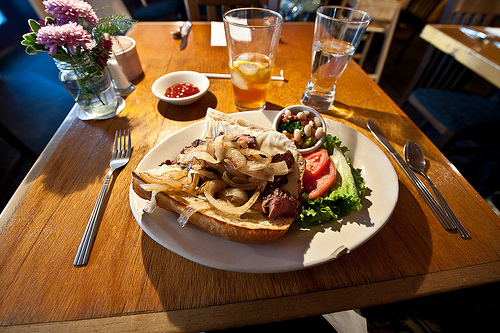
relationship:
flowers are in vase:
[20, 0, 133, 75] [50, 50, 126, 125]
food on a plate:
[135, 110, 367, 233] [129, 105, 402, 276]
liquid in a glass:
[231, 56, 271, 108] [220, 9, 280, 110]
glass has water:
[220, 9, 280, 110] [302, 4, 373, 110]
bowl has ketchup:
[152, 70, 208, 104] [164, 81, 198, 97]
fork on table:
[75, 125, 132, 267] [2, 11, 499, 323]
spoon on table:
[400, 138, 471, 240] [2, 11, 499, 323]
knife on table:
[365, 117, 456, 232] [2, 11, 499, 323]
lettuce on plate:
[284, 132, 368, 226] [129, 105, 402, 276]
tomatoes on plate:
[304, 148, 338, 199] [129, 105, 402, 276]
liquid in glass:
[231, 56, 271, 108] [220, 9, 280, 110]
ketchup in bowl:
[164, 81, 198, 97] [152, 70, 208, 104]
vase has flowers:
[50, 50, 126, 125] [20, 0, 133, 75]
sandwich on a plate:
[132, 106, 304, 240] [129, 105, 402, 276]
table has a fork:
[2, 11, 499, 323] [75, 125, 132, 267]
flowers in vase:
[20, 0, 133, 75] [50, 50, 126, 125]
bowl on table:
[152, 70, 208, 104] [2, 11, 499, 323]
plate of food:
[129, 105, 402, 276] [135, 110, 367, 233]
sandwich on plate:
[132, 106, 304, 240] [129, 105, 402, 276]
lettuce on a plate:
[284, 132, 368, 226] [129, 105, 402, 276]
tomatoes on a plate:
[304, 148, 338, 199] [129, 105, 402, 276]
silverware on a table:
[129, 105, 402, 276] [2, 11, 499, 323]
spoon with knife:
[400, 138, 471, 240] [365, 117, 456, 232]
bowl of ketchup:
[152, 70, 208, 104] [164, 81, 198, 97]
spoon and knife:
[400, 138, 471, 240] [365, 117, 456, 232]